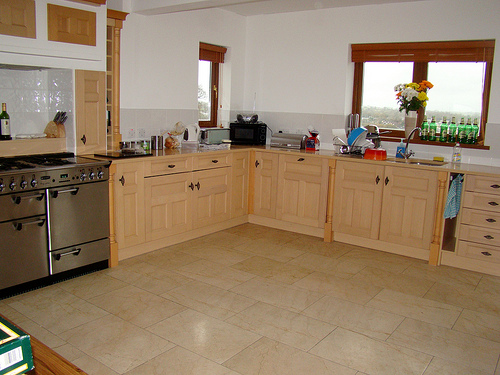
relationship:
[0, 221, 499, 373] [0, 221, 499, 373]
floor with floor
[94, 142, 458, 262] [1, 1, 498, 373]
wooden cupboards in kitchen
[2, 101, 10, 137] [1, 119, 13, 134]
bottle with label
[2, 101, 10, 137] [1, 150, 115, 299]
bottle behind stove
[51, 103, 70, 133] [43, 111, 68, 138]
knives in knives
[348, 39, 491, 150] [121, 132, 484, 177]
window above countertop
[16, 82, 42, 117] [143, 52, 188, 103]
tiles on wall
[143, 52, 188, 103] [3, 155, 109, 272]
wall behind stove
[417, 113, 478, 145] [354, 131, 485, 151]
bottles on sill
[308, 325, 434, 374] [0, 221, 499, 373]
tile on floor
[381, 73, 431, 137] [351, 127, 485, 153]
flowers on sill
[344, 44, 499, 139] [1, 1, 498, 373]
window in kitchen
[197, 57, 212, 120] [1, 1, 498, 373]
window in kitchen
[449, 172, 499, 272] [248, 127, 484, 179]
drawers under counter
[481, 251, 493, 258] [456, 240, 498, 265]
handle on drawer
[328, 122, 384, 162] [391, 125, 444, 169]
dishes next to sink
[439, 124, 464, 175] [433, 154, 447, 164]
bottle for dish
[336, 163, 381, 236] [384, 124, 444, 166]
door under sink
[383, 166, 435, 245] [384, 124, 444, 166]
door under sink